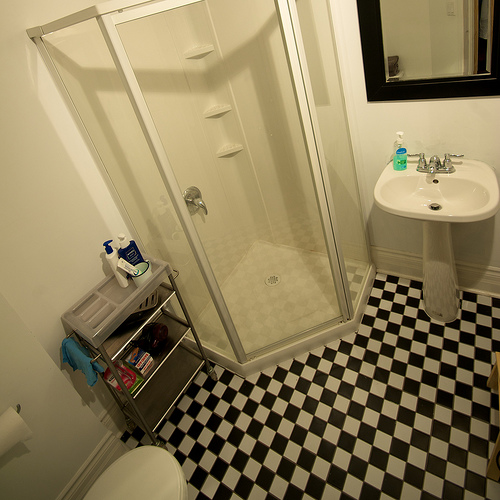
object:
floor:
[115, 264, 498, 497]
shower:
[40, 0, 342, 362]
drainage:
[265, 273, 281, 287]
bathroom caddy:
[60, 233, 215, 447]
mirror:
[354, 0, 500, 104]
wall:
[349, 2, 498, 148]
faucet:
[427, 155, 441, 174]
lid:
[78, 445, 188, 500]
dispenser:
[393, 131, 407, 171]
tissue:
[0, 406, 35, 457]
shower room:
[0, 0, 498, 498]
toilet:
[83, 444, 198, 499]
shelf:
[216, 143, 243, 159]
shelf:
[204, 104, 232, 120]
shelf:
[184, 42, 214, 58]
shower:
[25, 0, 378, 377]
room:
[2, 0, 500, 500]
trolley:
[160, 370, 184, 389]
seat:
[79, 445, 186, 499]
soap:
[393, 157, 406, 169]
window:
[90, 13, 346, 340]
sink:
[371, 150, 499, 223]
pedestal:
[421, 221, 456, 321]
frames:
[355, 0, 500, 104]